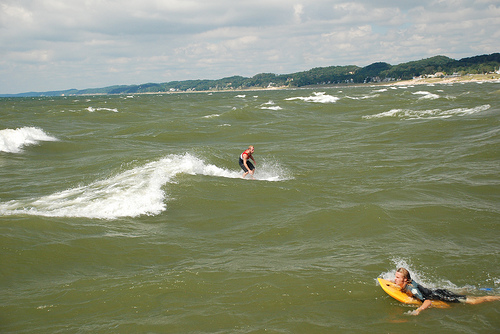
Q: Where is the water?
A: In the ocean.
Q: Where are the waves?
A: In the water.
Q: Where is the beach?
A: On the shore.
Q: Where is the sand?
A: On the bench.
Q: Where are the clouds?
A: In the sky.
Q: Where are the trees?
A: On land.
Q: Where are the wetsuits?
A: On the surfers.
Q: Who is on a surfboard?
A: A man.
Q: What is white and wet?
A: Water.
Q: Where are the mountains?
A: Behind the water.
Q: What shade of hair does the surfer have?
A: Blonde.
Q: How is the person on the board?
A: Laying down.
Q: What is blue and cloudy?
A: Sky.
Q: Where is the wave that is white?
A: Ocean.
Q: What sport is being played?
A: Bodyboarding.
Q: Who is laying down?
A: A man.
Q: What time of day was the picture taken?
A: Daytime.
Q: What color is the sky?
A: Blue.